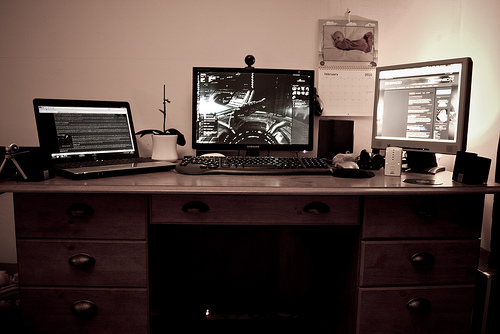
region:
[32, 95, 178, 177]
the opened laptop on the desk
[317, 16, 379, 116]
the calendar hanging on the wall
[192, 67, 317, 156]
the monitor on the desk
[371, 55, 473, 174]
the monitor on the desk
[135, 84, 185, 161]
the plant on the desk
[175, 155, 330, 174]
the keyboard on the desk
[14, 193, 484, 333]
the drawers in the desk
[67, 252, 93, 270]
the handle for the drawer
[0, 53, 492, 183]
the many objects on the desk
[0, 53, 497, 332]
the desk under the various objects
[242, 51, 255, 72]
a black webcam on a monitor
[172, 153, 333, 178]
a black computer keyboard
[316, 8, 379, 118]
a calendar on a wall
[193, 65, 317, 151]
a black computer monitor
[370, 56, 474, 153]
a grey computer monitor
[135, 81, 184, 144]
a small plant in a pot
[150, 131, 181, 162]
a small white pot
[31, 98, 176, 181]
a black and grey laptop computer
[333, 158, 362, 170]
a grey computer mouse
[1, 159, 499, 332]
a large wooden desk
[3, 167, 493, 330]
Wood desk in office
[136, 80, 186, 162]
Plant sitting on desk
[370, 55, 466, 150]
Computer monitor is on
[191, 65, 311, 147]
Computer monitor on desk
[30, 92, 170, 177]
Laptop sitting on desk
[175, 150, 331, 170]
Keyboard sitting on desk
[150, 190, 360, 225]
Middle drawer closed on desk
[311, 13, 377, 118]
Calendar hanging on wall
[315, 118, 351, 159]
Speakers on desk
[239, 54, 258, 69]
Camera on computer monitor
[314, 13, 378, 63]
a picture of baby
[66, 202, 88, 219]
a brass drawer pull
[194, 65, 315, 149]
a flat screen computer monitor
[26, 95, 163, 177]
a laptop on a desk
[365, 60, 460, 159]
a computer monitor on a desk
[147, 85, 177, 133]
a dead plant in a small vase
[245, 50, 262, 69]
a small round web camera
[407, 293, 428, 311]
a brass drawer pull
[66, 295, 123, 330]
a brass drawer pull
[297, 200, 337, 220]
a brass drawer pull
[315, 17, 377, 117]
calendar hanging on wall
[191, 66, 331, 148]
computer monitor against wall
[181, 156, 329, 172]
keyboard on desk top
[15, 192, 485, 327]
drawers on front of desk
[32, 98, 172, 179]
open laptop on desk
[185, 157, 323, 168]
black buttons on keyboard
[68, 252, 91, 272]
handle on wood drawer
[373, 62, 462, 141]
image on computer screen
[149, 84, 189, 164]
plant in white cup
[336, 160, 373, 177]
computer mouse on pad